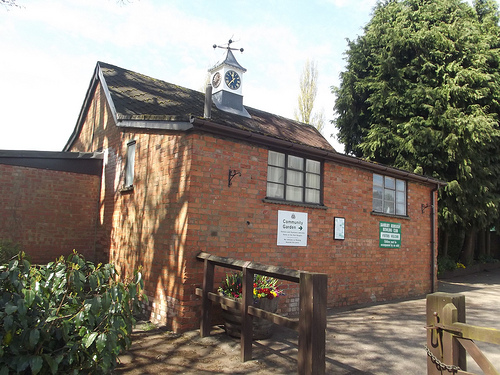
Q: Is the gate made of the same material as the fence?
A: Yes, both the gate and the fence are made of wood.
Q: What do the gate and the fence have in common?
A: The material, both the gate and the fence are wooden.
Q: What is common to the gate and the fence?
A: The material, both the gate and the fence are wooden.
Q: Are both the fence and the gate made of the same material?
A: Yes, both the fence and the gate are made of wood.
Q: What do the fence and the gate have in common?
A: The material, both the fence and the gate are wooden.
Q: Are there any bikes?
A: No, there are no bikes.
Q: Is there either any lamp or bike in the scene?
A: No, there are no bikes or lamps.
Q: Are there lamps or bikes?
A: No, there are no bikes or lamps.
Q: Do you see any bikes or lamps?
A: No, there are no bikes or lamps.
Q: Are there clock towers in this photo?
A: Yes, there is a clock tower.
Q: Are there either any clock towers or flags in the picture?
A: Yes, there is a clock tower.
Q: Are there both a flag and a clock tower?
A: No, there is a clock tower but no flags.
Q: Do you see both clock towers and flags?
A: No, there is a clock tower but no flags.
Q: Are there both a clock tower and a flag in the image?
A: No, there is a clock tower but no flags.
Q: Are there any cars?
A: No, there are no cars.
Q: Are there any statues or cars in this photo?
A: No, there are no cars or statues.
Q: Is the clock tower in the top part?
A: Yes, the clock tower is in the top of the image.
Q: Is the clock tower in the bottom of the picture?
A: No, the clock tower is in the top of the image.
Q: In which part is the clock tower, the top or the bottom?
A: The clock tower is in the top of the image.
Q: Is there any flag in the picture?
A: No, there are no flags.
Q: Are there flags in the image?
A: No, there are no flags.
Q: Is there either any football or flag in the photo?
A: No, there are no flags or footballs.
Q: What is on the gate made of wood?
A: The chain is on the gate.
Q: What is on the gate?
A: The chain is on the gate.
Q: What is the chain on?
A: The chain is on the gate.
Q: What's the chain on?
A: The chain is on the gate.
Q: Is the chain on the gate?
A: Yes, the chain is on the gate.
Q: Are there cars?
A: No, there are no cars.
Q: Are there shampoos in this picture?
A: No, there are no shampoos.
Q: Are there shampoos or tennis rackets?
A: No, there are no shampoos or tennis rackets.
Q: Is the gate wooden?
A: Yes, the gate is wooden.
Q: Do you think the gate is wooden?
A: Yes, the gate is wooden.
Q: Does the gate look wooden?
A: Yes, the gate is wooden.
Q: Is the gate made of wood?
A: Yes, the gate is made of wood.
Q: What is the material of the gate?
A: The gate is made of wood.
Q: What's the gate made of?
A: The gate is made of wood.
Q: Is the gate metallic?
A: No, the gate is wooden.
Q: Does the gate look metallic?
A: No, the gate is wooden.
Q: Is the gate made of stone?
A: No, the gate is made of wood.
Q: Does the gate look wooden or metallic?
A: The gate is wooden.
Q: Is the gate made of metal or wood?
A: The gate is made of wood.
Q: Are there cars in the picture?
A: No, there are no cars.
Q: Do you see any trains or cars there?
A: No, there are no cars or trains.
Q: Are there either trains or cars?
A: No, there are no cars or trains.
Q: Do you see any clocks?
A: Yes, there is a clock.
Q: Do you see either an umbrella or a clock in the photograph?
A: Yes, there is a clock.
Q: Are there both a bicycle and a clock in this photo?
A: No, there is a clock but no bicycles.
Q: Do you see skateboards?
A: No, there are no skateboards.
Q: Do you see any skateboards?
A: No, there are no skateboards.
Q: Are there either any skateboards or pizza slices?
A: No, there are no skateboards or pizza slices.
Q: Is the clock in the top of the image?
A: Yes, the clock is in the top of the image.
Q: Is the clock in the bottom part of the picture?
A: No, the clock is in the top of the image.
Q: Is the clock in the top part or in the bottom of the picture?
A: The clock is in the top of the image.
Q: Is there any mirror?
A: No, there are no mirrors.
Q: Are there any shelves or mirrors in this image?
A: No, there are no mirrors or shelves.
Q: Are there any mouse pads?
A: No, there are no mouse pads.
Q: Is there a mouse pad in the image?
A: No, there are no mouse pads.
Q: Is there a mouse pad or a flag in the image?
A: No, there are no mouse pads or flags.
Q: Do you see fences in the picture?
A: Yes, there is a fence.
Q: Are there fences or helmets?
A: Yes, there is a fence.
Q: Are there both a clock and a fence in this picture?
A: Yes, there are both a fence and a clock.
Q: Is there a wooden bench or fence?
A: Yes, there is a wood fence.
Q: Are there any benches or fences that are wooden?
A: Yes, the fence is wooden.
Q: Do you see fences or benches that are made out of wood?
A: Yes, the fence is made of wood.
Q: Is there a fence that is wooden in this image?
A: Yes, there is a wood fence.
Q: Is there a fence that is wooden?
A: Yes, there is a fence that is wooden.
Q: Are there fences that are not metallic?
A: Yes, there is a wooden fence.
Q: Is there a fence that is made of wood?
A: Yes, there is a fence that is made of wood.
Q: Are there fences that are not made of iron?
A: Yes, there is a fence that is made of wood.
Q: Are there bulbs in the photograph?
A: No, there are no bulbs.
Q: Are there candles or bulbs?
A: No, there are no bulbs or candles.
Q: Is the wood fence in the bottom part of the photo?
A: Yes, the fence is in the bottom of the image.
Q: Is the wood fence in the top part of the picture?
A: No, the fence is in the bottom of the image.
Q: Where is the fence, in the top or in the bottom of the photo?
A: The fence is in the bottom of the image.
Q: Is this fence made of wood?
A: Yes, the fence is made of wood.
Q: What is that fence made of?
A: The fence is made of wood.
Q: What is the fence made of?
A: The fence is made of wood.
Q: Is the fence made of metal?
A: No, the fence is made of wood.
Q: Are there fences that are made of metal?
A: No, there is a fence but it is made of wood.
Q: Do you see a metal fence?
A: No, there is a fence but it is made of wood.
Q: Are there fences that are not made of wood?
A: No, there is a fence but it is made of wood.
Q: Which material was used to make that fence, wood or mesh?
A: The fence is made of wood.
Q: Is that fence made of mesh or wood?
A: The fence is made of wood.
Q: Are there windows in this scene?
A: Yes, there is a window.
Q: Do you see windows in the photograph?
A: Yes, there is a window.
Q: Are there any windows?
A: Yes, there is a window.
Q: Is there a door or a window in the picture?
A: Yes, there is a window.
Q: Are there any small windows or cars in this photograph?
A: Yes, there is a small window.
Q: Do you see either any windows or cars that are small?
A: Yes, the window is small.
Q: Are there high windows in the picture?
A: Yes, there is a high window.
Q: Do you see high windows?
A: Yes, there is a high window.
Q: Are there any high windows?
A: Yes, there is a high window.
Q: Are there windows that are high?
A: Yes, there is a window that is high.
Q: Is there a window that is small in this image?
A: Yes, there is a small window.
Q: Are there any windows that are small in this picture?
A: Yes, there is a small window.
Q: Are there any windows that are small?
A: Yes, there is a window that is small.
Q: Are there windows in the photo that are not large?
A: Yes, there is a small window.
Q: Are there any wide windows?
A: Yes, there is a wide window.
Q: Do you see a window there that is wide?
A: Yes, there is a window that is wide.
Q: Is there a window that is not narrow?
A: Yes, there is a wide window.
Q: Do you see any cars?
A: No, there are no cars.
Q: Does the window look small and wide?
A: Yes, the window is small and wide.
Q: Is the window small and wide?
A: Yes, the window is small and wide.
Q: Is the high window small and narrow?
A: No, the window is small but wide.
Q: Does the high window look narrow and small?
A: No, the window is small but wide.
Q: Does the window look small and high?
A: Yes, the window is small and high.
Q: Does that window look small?
A: Yes, the window is small.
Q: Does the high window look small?
A: Yes, the window is small.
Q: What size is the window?
A: The window is small.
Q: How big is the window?
A: The window is small.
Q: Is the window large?
A: No, the window is small.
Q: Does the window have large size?
A: No, the window is small.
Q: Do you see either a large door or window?
A: No, there is a window but it is small.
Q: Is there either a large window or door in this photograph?
A: No, there is a window but it is small.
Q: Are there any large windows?
A: No, there is a window but it is small.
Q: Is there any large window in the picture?
A: No, there is a window but it is small.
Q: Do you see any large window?
A: No, there is a window but it is small.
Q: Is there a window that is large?
A: No, there is a window but it is small.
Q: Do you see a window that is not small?
A: No, there is a window but it is small.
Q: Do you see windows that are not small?
A: No, there is a window but it is small.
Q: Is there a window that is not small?
A: No, there is a window but it is small.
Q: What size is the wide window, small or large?
A: The window is small.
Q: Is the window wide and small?
A: Yes, the window is wide and small.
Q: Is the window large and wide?
A: No, the window is wide but small.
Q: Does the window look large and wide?
A: No, the window is wide but small.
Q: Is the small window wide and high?
A: Yes, the window is wide and high.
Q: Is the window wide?
A: Yes, the window is wide.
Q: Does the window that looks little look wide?
A: Yes, the window is wide.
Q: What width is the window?
A: The window is wide.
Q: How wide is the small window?
A: The window is wide.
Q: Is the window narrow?
A: No, the window is wide.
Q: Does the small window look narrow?
A: No, the window is wide.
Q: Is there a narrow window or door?
A: No, there is a window but it is wide.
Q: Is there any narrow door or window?
A: No, there is a window but it is wide.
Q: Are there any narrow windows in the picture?
A: No, there is a window but it is wide.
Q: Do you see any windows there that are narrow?
A: No, there is a window but it is wide.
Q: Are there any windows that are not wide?
A: No, there is a window but it is wide.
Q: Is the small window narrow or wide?
A: The window is wide.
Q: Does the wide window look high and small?
A: Yes, the window is high and small.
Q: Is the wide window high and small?
A: Yes, the window is high and small.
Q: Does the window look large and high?
A: No, the window is high but small.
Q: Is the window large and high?
A: No, the window is high but small.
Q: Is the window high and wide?
A: Yes, the window is high and wide.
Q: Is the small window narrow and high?
A: No, the window is high but wide.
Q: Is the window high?
A: Yes, the window is high.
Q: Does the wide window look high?
A: Yes, the window is high.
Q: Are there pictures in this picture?
A: No, there are no pictures.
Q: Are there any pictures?
A: No, there are no pictures.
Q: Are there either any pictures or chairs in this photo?
A: No, there are no pictures or chairs.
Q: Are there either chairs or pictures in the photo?
A: No, there are no pictures or chairs.